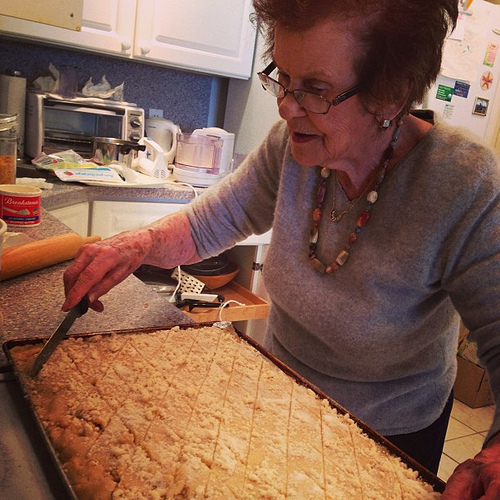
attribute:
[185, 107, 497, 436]
sweater — long sleeved, gray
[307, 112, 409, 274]
necklace — green, brown, white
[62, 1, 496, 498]
woman — old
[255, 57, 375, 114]
eyeglasses — woman's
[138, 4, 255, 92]
cabinets — pretty, white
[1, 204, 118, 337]
pin — rolling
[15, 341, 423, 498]
dessert — diagonally sliced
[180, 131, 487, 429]
shirt — gray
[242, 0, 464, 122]
hair — woman's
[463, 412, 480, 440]
tile — white, for floor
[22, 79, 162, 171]
toaster oven — silver, black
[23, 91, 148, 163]
oven — toaster